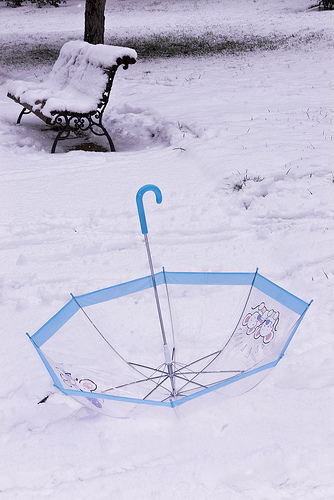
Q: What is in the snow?
A: An umbrella.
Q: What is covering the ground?
A: Snow.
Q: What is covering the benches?
A: Snow.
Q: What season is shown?
A: Winter.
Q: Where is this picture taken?
A: A park.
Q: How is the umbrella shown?
A: Upsidedown.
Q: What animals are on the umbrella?
A: Miice.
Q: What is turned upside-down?
A: An umbrella.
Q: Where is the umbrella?
A: On the ground.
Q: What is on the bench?
A: Snow.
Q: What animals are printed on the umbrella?
A: Mice.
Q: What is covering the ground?
A: Snow.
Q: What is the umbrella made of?
A: Plastic.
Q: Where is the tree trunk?
A: Behind the bench.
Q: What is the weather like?
A: Cold and snowy.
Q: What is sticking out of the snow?
A: Blades of grass.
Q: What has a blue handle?
A: The umbrella.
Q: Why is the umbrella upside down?
A: Nobody is holding it.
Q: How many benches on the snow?
A: One.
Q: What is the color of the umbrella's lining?
A: Blue.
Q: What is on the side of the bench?
A: A tree.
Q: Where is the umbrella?
A: On the snow.